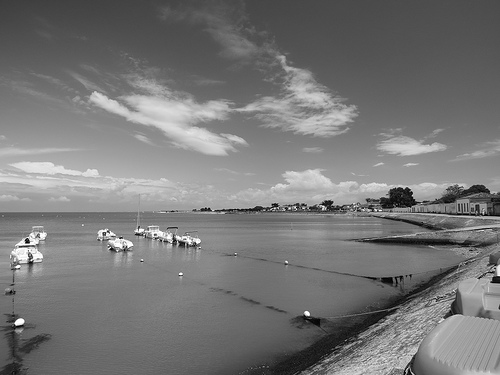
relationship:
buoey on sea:
[177, 272, 183, 276] [2, 211, 394, 308]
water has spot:
[61, 285, 182, 358] [209, 284, 226, 294]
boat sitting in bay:
[107, 236, 134, 253] [0, 211, 486, 373]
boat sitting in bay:
[99, 223, 117, 242] [0, 211, 486, 373]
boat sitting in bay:
[177, 232, 202, 249] [0, 211, 486, 373]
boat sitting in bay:
[143, 224, 163, 242] [0, 211, 486, 373]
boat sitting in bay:
[8, 245, 42, 263] [0, 211, 486, 373]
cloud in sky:
[0, 0, 499, 212] [2, 2, 498, 210]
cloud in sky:
[0, 0, 499, 212] [83, 55, 249, 164]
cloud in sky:
[73, 7, 356, 157] [2, 2, 498, 210]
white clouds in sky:
[16, 55, 251, 159] [2, 2, 498, 210]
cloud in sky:
[0, 0, 499, 212] [377, 21, 480, 136]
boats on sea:
[9, 213, 208, 293] [0, 202, 483, 368]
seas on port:
[105, 247, 348, 356] [318, 267, 500, 367]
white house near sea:
[454, 191, 499, 217] [0, 202, 483, 368]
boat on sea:
[9, 244, 43, 263] [0, 202, 483, 368]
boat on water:
[107, 238, 136, 254] [34, 208, 415, 332]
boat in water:
[107, 236, 134, 253] [108, 288, 230, 343]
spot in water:
[304, 262, 339, 281] [4, 198, 490, 372]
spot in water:
[221, 283, 270, 313] [4, 198, 490, 372]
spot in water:
[316, 251, 396, 271] [118, 290, 200, 349]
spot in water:
[291, 309, 368, 334] [99, 299, 212, 354]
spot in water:
[238, 289, 265, 311] [4, 198, 490, 372]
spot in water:
[238, 292, 266, 310] [1, 215, 355, 370]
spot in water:
[52, 271, 92, 281] [2, 211, 468, 370]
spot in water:
[363, 266, 407, 298] [4, 213, 429, 366]